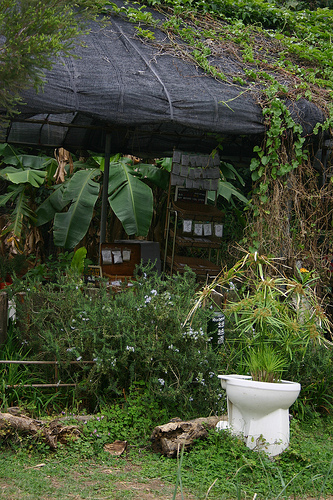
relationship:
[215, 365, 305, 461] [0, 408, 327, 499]
toilet on top of grass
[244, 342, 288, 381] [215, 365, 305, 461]
plant sprouting from seat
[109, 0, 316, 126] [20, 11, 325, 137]
ivy on top of roof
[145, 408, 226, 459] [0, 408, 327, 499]
logs on top of ground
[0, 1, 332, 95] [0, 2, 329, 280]
plants on top of umbrella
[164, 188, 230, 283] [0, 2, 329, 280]
shelves are under umbrella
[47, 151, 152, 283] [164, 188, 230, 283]
plants next to shelves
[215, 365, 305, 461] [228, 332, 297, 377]
toilet has a plant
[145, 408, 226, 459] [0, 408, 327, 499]
tree on top of ground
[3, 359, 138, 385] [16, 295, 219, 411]
fence along plants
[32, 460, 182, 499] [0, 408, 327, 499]
dirt on top of ground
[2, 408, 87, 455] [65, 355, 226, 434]
log by weeds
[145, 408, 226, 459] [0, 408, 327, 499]
log on top of ground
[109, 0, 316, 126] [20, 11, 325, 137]
leaves on top of roof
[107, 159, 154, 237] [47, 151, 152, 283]
banana leaf from banana tree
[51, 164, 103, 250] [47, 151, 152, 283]
banana tree from banana tree